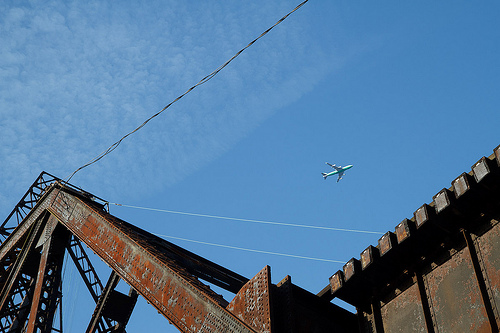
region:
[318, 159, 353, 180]
an airplane in the sky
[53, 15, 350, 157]
a wire in the sky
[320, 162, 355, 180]
an airplane flying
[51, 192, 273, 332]
a steel beam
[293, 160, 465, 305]
part of a building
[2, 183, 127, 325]
the top of a bridge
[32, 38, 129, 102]
clouds in the sky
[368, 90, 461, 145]
blue of the sky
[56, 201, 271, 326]
rusty steel on the beam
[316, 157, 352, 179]
an airplane that is flying above a building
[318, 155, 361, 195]
a large plane flying in the sky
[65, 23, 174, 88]
some partialy cloudy skies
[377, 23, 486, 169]
some very clear skies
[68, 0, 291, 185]
a large metal cable attached to the bridge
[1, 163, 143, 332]
a large bridge support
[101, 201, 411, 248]
some metal cables attached to the bridge support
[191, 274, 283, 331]
some rusty metal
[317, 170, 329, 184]
the tail of a large plane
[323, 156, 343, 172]
a wing of a large plane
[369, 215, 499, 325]
some metal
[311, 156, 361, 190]
plane in the sky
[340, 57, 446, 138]
blue sky in the distance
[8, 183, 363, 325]
metal contraption in the sky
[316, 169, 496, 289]
roof of a building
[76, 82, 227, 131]
electrical wire in the sky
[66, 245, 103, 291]
metal ladder attached to contraption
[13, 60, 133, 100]
white clouds in sky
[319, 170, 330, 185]
tail of a plane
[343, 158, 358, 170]
nose of a plane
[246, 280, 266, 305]
rivets in metal structure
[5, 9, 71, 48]
white clouds in blue sky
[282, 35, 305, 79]
white clouds in blue sky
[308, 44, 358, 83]
white clouds in blue sky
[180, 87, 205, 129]
white clouds in blue sky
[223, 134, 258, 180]
white clouds in blue sky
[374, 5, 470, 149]
white clouds in blue sky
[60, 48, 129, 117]
white clouds in blue sky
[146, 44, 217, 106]
white clouds in blue sky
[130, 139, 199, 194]
white clouds in blue sky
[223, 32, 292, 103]
white clouds in blue sky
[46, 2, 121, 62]
white clouds in blue sky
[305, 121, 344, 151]
white clouds in blue sky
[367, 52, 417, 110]
white clouds in blue sky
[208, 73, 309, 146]
white clouds in blue sky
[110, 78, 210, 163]
white clouds in blue sky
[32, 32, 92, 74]
white clouds in blue sky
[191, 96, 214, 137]
white clouds in blue sky